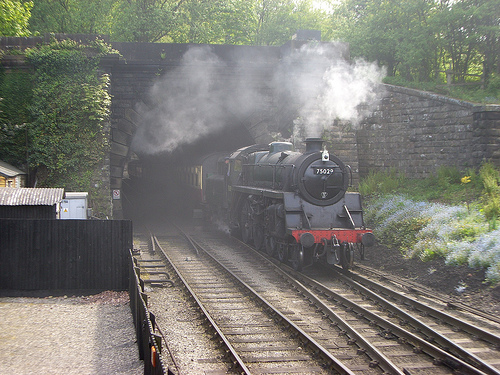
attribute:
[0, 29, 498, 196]
overpath — brick